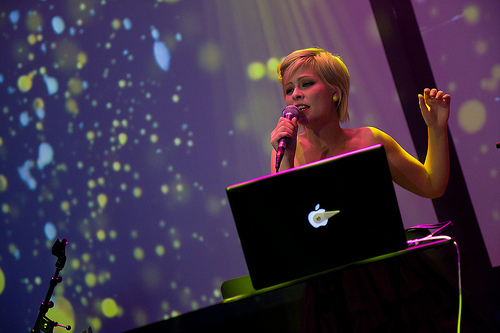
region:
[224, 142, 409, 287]
computer laptop screen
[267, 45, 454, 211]
a girl singing into microphone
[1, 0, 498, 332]
projected light designs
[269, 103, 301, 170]
hand holding microphone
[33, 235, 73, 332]
neck of a musical instrument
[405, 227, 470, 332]
electrical power cord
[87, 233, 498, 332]
long black podium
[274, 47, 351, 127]
woman's blonde hair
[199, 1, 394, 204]
rays of light shining down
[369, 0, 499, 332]
large support pillar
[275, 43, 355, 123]
woman with straight blonde hair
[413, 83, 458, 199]
woman's left arm held upright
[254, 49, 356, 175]
blonde woman holding microphone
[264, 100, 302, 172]
one Caucasian right hand holding microphone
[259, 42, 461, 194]
white woman singing into microphone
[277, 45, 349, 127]
woman wearing large pearl earring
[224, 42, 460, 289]
woman on stage in front of laptop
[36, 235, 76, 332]
one shadowed microphone stand on stage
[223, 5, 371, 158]
woman singing in front of white gauzy curtains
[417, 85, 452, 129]
five bent fingers on woman's hand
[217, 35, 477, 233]
the woman is holding a mic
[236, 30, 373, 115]
the woman`s hair is blonde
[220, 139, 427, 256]
the laptop is on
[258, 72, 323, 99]
the eyes are open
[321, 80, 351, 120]
the woman is wearing earrings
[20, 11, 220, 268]
dots are on the walls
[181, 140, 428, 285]
the laptop is black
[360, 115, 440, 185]
the light is on the arm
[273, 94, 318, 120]
the woman is wearing lipstick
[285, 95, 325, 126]
the woman`s teeth are showing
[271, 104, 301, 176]
Hand holding a microphone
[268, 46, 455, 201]
Woman holding a microphone in her hand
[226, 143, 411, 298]
Apple computer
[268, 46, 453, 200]
Woman with short hair and light colored earings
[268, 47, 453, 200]
Woman with no visible clothing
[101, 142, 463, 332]
table with apple laptop on it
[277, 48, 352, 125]
short blond hair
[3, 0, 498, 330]
wall with random blue and green splotches on it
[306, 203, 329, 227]
white Apple logo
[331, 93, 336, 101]
round light colored earing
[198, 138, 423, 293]
open black laptop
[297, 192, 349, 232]
white apple logo on back of black laptop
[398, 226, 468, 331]
white wire coming out of black laptop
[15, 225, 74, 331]
top of instrument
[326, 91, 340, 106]
one pearl earring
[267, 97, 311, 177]
black microphone in hand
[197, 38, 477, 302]
woman holding a microphone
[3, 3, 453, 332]
purple screen in background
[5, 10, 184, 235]
blue and green splotches on purple screen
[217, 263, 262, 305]
top of black chair in front of black table